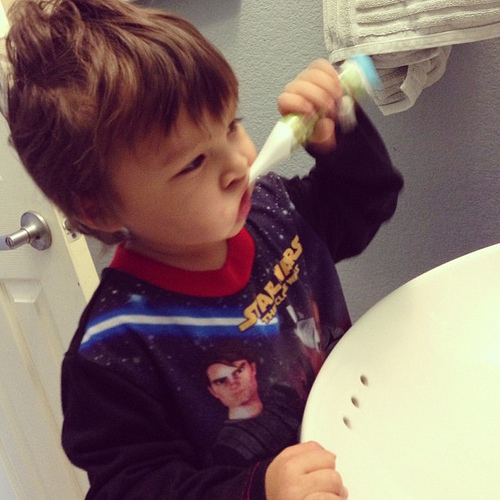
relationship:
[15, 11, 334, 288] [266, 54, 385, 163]
boy using brush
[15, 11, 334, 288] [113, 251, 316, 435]
boy wearing shirt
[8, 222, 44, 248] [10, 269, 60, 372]
knob on door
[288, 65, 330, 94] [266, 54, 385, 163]
hand on brush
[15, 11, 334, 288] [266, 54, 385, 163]
boy holding brush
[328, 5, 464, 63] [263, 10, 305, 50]
towel on wall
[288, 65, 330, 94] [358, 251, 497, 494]
hand in sink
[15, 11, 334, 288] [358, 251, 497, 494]
boy in sink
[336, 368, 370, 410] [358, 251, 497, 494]
holes in sink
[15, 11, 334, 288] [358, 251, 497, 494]
boy using sink